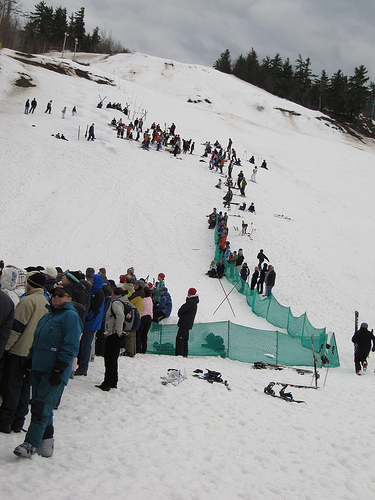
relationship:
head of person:
[49, 279, 74, 308] [12, 279, 83, 459]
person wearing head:
[175, 287, 200, 358] [186, 287, 196, 295]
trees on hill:
[2, 1, 119, 54] [0, 45, 374, 225]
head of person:
[186, 287, 196, 295] [175, 287, 200, 358]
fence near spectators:
[130, 214, 340, 369] [0, 184, 374, 463]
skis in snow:
[274, 378, 319, 389] [177, 372, 252, 447]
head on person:
[110, 284, 124, 298] [95, 286, 140, 390]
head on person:
[98, 266, 104, 274] [97, 265, 107, 281]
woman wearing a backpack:
[98, 283, 128, 398] [119, 300, 136, 335]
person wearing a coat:
[0, 272, 53, 435] [2, 288, 49, 358]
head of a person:
[359, 321, 368, 331] [94, 283, 142, 392]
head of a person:
[359, 321, 368, 331] [266, 261, 279, 294]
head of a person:
[359, 321, 368, 331] [346, 314, 374, 377]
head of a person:
[157, 271, 166, 280] [155, 268, 166, 290]